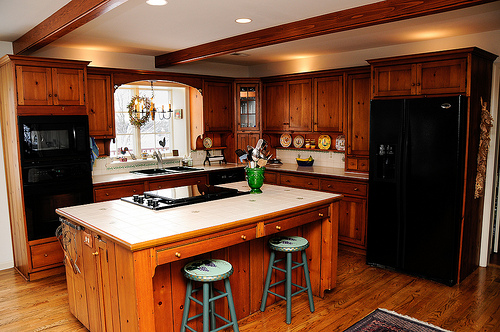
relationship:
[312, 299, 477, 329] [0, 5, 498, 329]
carpet in kitchen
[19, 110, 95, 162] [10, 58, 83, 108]
microwave under cabinet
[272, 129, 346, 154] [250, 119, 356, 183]
plates on shelf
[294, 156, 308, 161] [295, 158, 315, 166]
banana on basket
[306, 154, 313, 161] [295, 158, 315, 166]
banana on basket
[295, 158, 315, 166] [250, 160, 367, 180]
basket on counter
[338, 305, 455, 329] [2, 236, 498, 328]
rug on floor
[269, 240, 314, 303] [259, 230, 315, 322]
stool in kitchen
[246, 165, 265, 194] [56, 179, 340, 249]
vase on counter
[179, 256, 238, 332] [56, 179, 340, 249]
bar stool under counter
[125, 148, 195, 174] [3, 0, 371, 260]
sink in kitchen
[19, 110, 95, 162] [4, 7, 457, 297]
microwave in kitchen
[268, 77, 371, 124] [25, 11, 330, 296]
brown cabinets in kitchen